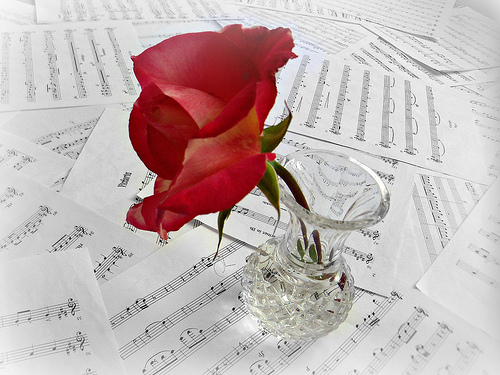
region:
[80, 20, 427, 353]
Open red rose in vase.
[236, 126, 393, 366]
Crystal urn shaped clear vase.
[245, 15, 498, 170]
Array of different music sheets.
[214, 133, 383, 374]
Vase sitting on music sheets.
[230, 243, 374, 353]
Diamond cut out pattern on vase.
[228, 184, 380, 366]
Vase half filled with water.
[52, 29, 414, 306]
this is a rose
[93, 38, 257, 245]
the flower is red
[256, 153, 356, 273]
the stem is green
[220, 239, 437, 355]
the vase is glass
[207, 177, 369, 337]
this is a vase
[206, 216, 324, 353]
the vase is clear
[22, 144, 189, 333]
these are music sheets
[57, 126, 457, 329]
the sheets are scattered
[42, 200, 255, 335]
the sheets are white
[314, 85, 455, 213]
the writing is black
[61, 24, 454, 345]
this is a flower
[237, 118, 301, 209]
the leaves are green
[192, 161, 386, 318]
this flower is alone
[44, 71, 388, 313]
flower on music sheets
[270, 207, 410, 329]
the vase is fancy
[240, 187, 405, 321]
the vase is glasswork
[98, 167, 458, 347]
the vase has water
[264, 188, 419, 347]
the vase is clear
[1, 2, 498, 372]
music on sheets of paper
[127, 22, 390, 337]
red flower in crystal vase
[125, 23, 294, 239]
red petals of flower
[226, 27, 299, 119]
uneven edge of flower petal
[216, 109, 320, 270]
stem and leaves of flower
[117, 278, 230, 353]
musical notes on white paper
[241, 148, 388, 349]
stem inside of vase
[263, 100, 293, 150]
bent tip of leaf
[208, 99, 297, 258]
three green leaves of flower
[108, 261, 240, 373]
musical notes on bars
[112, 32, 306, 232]
the rose is red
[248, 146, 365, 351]
the vase is clear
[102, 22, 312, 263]
Red rose that is starting to wilt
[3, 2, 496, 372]
Red rose sitting in vase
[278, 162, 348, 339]
Stem of flower sitting in water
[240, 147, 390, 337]
Cut glass vase on top of sheet music